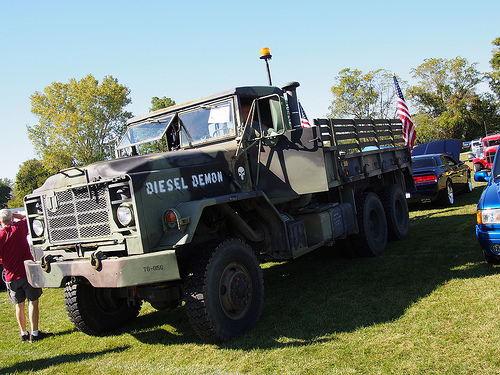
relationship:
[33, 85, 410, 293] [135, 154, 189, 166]
truck in colors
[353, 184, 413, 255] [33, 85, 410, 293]
wheels on truck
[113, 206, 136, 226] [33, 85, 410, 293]
lights of truck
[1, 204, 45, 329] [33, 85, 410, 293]
man by truck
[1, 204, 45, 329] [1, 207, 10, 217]
man wearing hat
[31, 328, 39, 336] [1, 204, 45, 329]
socks of man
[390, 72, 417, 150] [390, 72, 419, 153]
flag of states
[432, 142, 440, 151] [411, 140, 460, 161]
black car hood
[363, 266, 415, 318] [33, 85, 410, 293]
grass under truck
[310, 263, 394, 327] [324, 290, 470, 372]
shadow on ground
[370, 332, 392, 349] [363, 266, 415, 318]
spots on grass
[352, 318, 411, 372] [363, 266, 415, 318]
cut green grass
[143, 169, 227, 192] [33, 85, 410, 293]
words on truck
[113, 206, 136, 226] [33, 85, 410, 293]
lights on truck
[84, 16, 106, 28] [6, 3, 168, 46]
blue skies overhead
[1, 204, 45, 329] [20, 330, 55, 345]
man wearing sneakers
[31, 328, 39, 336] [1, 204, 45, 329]
socks on man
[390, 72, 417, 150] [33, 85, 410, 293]
flag on truck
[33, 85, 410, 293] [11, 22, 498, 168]
truck in background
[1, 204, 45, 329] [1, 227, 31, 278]
man in shirt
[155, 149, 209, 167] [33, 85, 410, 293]
military diesel truck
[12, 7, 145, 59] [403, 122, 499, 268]
daytime auto show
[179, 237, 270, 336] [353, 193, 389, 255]
wheel and wheels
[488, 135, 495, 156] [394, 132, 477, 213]
red behind diesel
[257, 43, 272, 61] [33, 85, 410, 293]
bubble above truck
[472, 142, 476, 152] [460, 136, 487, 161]
white in distance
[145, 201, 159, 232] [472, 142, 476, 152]
green and white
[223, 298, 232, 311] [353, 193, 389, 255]
gray vehicle wheels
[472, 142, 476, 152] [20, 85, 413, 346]
white on truck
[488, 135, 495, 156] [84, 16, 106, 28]
red white blue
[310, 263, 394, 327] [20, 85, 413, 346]
shadow of truck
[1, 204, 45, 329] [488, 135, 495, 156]
man wearing red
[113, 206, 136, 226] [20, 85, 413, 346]
lights on truck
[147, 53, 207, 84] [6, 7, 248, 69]
clouds against sky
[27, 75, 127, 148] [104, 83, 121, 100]
tree with leaves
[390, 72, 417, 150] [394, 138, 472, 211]
flag to diesel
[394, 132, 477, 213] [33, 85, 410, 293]
diesel on truck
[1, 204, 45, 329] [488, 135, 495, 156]
man with red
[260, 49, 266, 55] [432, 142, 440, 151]
orange and black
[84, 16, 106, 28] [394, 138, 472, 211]
blue sedan diesel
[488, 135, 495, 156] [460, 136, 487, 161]
red in distance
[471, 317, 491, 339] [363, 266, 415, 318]
light green grass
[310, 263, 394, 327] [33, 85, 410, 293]
shadow from truck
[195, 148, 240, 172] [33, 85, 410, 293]
camo armored truck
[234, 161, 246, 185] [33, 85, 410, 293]
skull on truck